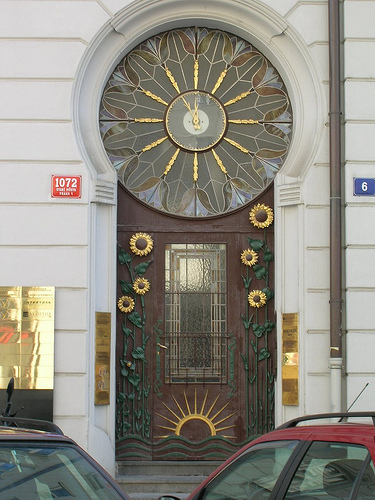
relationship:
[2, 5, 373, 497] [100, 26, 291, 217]
building has a clock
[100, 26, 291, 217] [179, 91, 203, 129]
clock has hands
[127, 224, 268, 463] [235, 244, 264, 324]
door has flowers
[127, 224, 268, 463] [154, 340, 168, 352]
door has a handle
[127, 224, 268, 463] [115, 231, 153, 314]
door has daisies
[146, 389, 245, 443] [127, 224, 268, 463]
sun on bottom of door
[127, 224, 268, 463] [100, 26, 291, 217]
door has a clock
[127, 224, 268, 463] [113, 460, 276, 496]
door has steps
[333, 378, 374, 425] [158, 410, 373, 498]
antenna for a car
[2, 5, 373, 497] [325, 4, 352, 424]
building has a pipe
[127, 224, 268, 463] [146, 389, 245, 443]
door has a sun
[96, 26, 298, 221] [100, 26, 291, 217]
window has a clock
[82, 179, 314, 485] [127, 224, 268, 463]
frame of a door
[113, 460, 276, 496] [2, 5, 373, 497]
steps to building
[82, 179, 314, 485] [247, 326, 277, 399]
frame has a green leaf